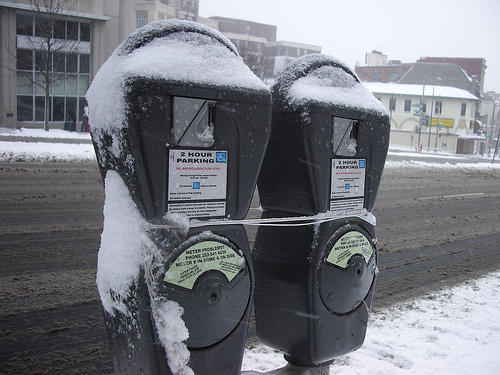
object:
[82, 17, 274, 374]
meter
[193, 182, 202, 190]
stickers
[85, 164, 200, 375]
snow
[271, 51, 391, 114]
snow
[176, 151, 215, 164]
2-hour parking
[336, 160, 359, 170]
2-hour parking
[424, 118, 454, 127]
sign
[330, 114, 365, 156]
poster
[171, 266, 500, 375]
snow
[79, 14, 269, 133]
snow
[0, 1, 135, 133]
brown building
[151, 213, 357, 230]
strings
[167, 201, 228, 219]
white sticker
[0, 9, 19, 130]
wall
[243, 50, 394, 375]
meter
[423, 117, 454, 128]
banner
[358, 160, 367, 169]
handicapped sign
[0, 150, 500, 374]
road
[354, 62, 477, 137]
building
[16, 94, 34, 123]
windows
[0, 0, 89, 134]
tree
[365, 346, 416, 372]
footprint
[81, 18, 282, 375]
machines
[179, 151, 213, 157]
words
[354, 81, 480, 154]
building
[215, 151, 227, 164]
handicap sign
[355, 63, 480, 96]
roof